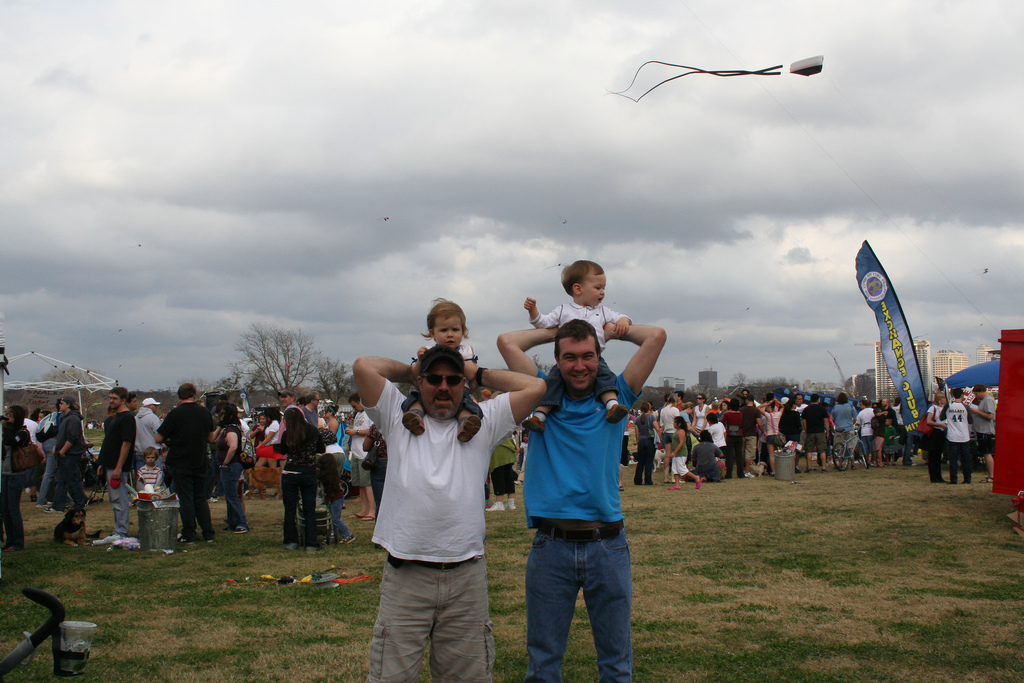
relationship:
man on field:
[351, 345, 549, 682] [1, 427, 1022, 680]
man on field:
[495, 320, 668, 682] [1, 427, 1022, 680]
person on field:
[272, 403, 327, 550] [1, 427, 1022, 680]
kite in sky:
[605, 54, 822, 103] [4, 4, 1022, 390]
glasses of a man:
[417, 363, 479, 395] [331, 336, 559, 678]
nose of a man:
[427, 372, 463, 399] [302, 317, 558, 679]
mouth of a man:
[395, 377, 473, 415] [324, 345, 543, 678]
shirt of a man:
[354, 360, 539, 577] [331, 336, 559, 678]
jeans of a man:
[520, 510, 680, 679] [482, 304, 680, 679]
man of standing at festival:
[351, 345, 549, 682] [15, 235, 1022, 669]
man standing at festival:
[495, 320, 668, 682] [15, 235, 1022, 669]